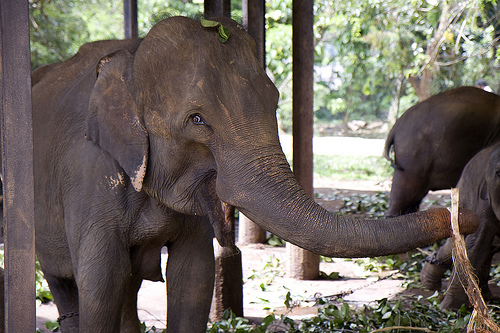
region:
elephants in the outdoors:
[32, 6, 484, 331]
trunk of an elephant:
[239, 153, 483, 271]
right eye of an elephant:
[178, 110, 217, 135]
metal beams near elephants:
[281, 8, 334, 209]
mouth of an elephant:
[192, 171, 254, 253]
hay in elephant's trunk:
[442, 198, 493, 310]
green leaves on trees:
[329, 6, 415, 108]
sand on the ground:
[254, 251, 301, 301]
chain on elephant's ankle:
[50, 303, 81, 328]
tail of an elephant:
[377, 126, 409, 175]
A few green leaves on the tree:
[333, 310, 353, 329]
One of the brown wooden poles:
[287, 55, 324, 152]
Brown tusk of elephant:
[348, 195, 441, 265]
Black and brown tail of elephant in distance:
[382, 133, 403, 178]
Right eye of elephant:
[186, 108, 206, 131]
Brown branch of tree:
[435, 21, 457, 52]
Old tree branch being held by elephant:
[452, 237, 481, 292]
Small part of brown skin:
[451, 98, 471, 120]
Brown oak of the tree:
[343, 115, 350, 130]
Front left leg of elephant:
[168, 271, 208, 331]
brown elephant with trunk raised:
[36, 9, 466, 329]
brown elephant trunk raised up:
[213, 110, 485, 292]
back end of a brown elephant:
[371, 65, 476, 211]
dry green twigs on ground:
[305, 282, 448, 329]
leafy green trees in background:
[317, 15, 476, 95]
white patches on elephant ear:
[102, 135, 168, 217]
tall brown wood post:
[279, 14, 344, 277]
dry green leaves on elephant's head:
[177, 6, 277, 61]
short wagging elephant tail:
[377, 120, 412, 183]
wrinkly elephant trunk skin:
[238, 124, 425, 248]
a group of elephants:
[31, 7, 496, 329]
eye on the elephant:
[185, 104, 220, 142]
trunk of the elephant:
[265, 122, 455, 282]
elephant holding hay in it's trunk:
[175, 71, 482, 312]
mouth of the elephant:
[182, 160, 257, 259]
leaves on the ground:
[326, 295, 410, 332]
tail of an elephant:
[372, 83, 409, 175]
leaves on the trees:
[385, 13, 434, 73]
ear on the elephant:
[85, 55, 159, 192]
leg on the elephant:
[174, 249, 220, 317]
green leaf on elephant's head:
[183, 7, 236, 49]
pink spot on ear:
[117, 128, 150, 196]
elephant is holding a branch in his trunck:
[380, 177, 490, 322]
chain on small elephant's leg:
[305, 251, 442, 292]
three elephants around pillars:
[27, 11, 495, 296]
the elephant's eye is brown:
[170, 107, 225, 138]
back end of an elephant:
[376, 98, 441, 208]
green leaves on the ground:
[327, 300, 448, 330]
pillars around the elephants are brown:
[207, 223, 323, 315]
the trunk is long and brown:
[261, 171, 478, 268]